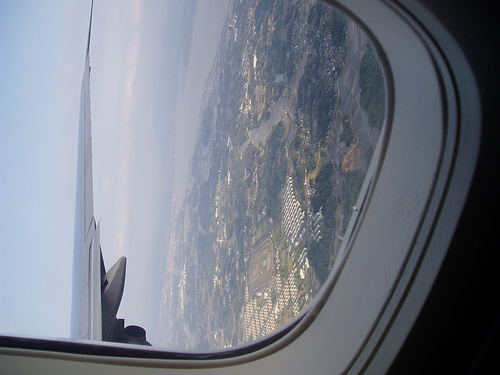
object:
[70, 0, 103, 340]
wing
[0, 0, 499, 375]
airplane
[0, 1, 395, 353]
window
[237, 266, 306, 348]
ground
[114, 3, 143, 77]
cloud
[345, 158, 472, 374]
lines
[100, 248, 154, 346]
engine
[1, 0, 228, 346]
sky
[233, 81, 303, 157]
river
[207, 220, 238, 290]
structures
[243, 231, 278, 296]
form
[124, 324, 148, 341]
cylinder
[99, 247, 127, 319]
protrusion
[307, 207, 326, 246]
houses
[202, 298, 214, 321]
farm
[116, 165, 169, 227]
clouds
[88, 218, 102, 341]
flap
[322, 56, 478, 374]
edge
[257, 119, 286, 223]
trees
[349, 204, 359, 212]
rivet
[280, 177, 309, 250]
buildings